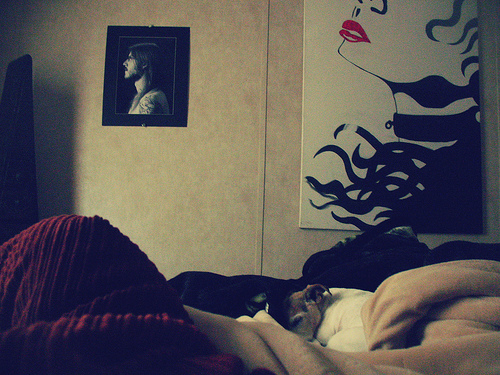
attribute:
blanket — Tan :
[233, 315, 342, 359]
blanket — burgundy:
[3, 233, 125, 371]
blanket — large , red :
[0, 185, 296, 373]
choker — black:
[384, 74, 489, 143]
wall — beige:
[9, 6, 493, 280]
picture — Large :
[98, 19, 198, 134]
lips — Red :
[337, 15, 374, 47]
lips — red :
[336, 13, 373, 48]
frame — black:
[99, 21, 194, 135]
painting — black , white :
[285, 18, 492, 243]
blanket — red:
[33, 242, 133, 360]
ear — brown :
[305, 281, 332, 298]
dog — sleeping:
[279, 280, 379, 357]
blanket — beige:
[182, 250, 498, 370]